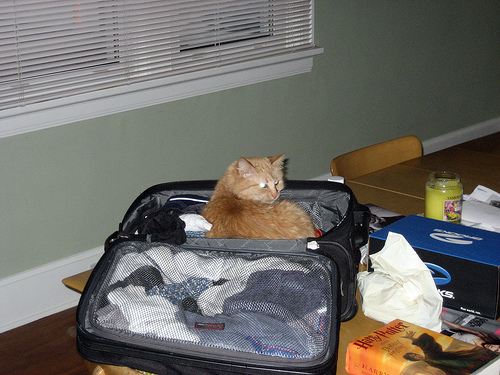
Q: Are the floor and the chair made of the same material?
A: Yes, both the floor and the chair are made of wood.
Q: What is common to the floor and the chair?
A: The material, both the floor and the chair are wooden.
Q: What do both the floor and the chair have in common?
A: The material, both the floor and the chair are wooden.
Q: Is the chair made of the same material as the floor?
A: Yes, both the chair and the floor are made of wood.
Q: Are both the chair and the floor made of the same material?
A: Yes, both the chair and the floor are made of wood.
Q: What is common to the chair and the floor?
A: The material, both the chair and the floor are wooden.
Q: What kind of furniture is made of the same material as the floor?
A: The chair is made of the same material as the floor.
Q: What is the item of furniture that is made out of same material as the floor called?
A: The piece of furniture is a chair.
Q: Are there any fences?
A: No, there are no fences.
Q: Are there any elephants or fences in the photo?
A: No, there are no fences or elephants.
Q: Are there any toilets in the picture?
A: No, there are no toilets.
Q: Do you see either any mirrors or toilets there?
A: No, there are no toilets or mirrors.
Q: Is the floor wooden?
A: Yes, the floor is wooden.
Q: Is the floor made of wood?
A: Yes, the floor is made of wood.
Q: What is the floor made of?
A: The floor is made of wood.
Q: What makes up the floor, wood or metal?
A: The floor is made of wood.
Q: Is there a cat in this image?
A: Yes, there is a cat.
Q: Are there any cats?
A: Yes, there is a cat.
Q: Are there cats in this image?
A: Yes, there is a cat.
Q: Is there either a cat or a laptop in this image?
A: Yes, there is a cat.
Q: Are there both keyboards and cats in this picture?
A: No, there is a cat but no keyboards.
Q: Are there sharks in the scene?
A: No, there are no sharks.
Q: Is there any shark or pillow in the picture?
A: No, there are no sharks or pillows.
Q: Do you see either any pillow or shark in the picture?
A: No, there are no sharks or pillows.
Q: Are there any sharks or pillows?
A: No, there are no sharks or pillows.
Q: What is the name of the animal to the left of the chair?
A: The animal is a cat.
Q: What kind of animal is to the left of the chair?
A: The animal is a cat.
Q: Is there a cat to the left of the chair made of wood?
A: Yes, there is a cat to the left of the chair.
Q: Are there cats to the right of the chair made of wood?
A: No, the cat is to the left of the chair.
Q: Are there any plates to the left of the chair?
A: No, there is a cat to the left of the chair.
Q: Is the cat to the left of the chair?
A: Yes, the cat is to the left of the chair.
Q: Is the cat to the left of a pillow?
A: No, the cat is to the left of the chair.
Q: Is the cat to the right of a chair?
A: No, the cat is to the left of a chair.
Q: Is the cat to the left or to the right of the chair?
A: The cat is to the left of the chair.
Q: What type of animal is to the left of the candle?
A: The animal is a cat.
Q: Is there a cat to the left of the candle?
A: Yes, there is a cat to the left of the candle.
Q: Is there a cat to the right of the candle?
A: No, the cat is to the left of the candle.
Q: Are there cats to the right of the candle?
A: No, the cat is to the left of the candle.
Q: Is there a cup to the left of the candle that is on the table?
A: No, there is a cat to the left of the candle.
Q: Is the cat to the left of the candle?
A: Yes, the cat is to the left of the candle.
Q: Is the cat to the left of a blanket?
A: No, the cat is to the left of the candle.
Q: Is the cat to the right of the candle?
A: No, the cat is to the left of the candle.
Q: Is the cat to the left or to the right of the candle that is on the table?
A: The cat is to the left of the candle.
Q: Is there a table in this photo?
A: Yes, there is a table.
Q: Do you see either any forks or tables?
A: Yes, there is a table.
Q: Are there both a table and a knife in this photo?
A: No, there is a table but no knives.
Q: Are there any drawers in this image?
A: No, there are no drawers.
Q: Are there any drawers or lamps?
A: No, there are no drawers or lamps.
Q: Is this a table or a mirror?
A: This is a table.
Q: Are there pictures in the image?
A: No, there are no pictures.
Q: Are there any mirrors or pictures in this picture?
A: No, there are no pictures or mirrors.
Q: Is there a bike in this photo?
A: No, there are no bikes.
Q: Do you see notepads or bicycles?
A: No, there are no bicycles or notepads.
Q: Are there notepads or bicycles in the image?
A: No, there are no bicycles or notepads.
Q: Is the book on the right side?
A: Yes, the book is on the right of the image.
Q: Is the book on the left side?
A: No, the book is on the right of the image.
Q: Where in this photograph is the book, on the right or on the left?
A: The book is on the right of the image.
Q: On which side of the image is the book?
A: The book is on the right of the image.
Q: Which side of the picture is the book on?
A: The book is on the right of the image.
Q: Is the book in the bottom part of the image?
A: Yes, the book is in the bottom of the image.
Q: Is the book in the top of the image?
A: No, the book is in the bottom of the image.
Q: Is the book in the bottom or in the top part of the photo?
A: The book is in the bottom of the image.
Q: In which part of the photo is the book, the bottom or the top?
A: The book is in the bottom of the image.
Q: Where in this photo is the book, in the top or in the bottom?
A: The book is in the bottom of the image.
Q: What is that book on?
A: The book is on the table.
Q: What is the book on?
A: The book is on the table.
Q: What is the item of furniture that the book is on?
A: The piece of furniture is a table.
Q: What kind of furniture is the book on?
A: The book is on the table.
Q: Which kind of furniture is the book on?
A: The book is on the table.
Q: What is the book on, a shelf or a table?
A: The book is on a table.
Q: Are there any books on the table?
A: Yes, there is a book on the table.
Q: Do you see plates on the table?
A: No, there is a book on the table.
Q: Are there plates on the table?
A: No, there is a book on the table.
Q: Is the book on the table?
A: Yes, the book is on the table.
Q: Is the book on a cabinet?
A: No, the book is on the table.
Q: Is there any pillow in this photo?
A: No, there are no pillows.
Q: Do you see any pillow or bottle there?
A: No, there are no pillows or bottles.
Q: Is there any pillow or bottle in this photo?
A: No, there are no pillows or bottles.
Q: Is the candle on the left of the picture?
A: No, the candle is on the right of the image.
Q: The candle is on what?
A: The candle is on the table.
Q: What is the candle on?
A: The candle is on the table.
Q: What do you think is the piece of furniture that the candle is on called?
A: The piece of furniture is a table.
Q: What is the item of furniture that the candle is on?
A: The piece of furniture is a table.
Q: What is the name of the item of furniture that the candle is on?
A: The piece of furniture is a table.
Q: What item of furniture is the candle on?
A: The candle is on the table.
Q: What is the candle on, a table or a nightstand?
A: The candle is on a table.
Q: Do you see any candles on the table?
A: Yes, there is a candle on the table.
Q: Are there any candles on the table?
A: Yes, there is a candle on the table.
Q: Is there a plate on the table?
A: No, there is a candle on the table.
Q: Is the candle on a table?
A: Yes, the candle is on a table.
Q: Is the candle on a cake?
A: No, the candle is on a table.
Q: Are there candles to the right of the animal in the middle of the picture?
A: Yes, there is a candle to the right of the cat.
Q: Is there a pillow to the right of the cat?
A: No, there is a candle to the right of the cat.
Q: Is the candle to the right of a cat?
A: Yes, the candle is to the right of a cat.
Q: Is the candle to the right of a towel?
A: No, the candle is to the right of a cat.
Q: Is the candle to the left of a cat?
A: No, the candle is to the right of a cat.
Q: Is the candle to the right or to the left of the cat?
A: The candle is to the right of the cat.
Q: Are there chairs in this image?
A: Yes, there is a chair.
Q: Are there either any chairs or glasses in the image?
A: Yes, there is a chair.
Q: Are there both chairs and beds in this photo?
A: No, there is a chair but no beds.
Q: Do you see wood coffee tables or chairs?
A: Yes, there is a wood chair.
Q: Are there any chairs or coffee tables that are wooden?
A: Yes, the chair is wooden.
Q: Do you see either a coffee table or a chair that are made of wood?
A: Yes, the chair is made of wood.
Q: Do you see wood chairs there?
A: Yes, there is a wood chair.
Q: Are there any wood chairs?
A: Yes, there is a wood chair.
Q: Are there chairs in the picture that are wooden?
A: Yes, there is a chair that is wooden.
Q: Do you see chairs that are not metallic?
A: Yes, there is a wooden chair.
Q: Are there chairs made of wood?
A: Yes, there is a chair that is made of wood.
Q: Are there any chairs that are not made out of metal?
A: Yes, there is a chair that is made of wood.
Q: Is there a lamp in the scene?
A: No, there are no lamps.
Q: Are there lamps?
A: No, there are no lamps.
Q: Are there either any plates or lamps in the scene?
A: No, there are no lamps or plates.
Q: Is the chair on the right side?
A: Yes, the chair is on the right of the image.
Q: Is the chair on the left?
A: No, the chair is on the right of the image.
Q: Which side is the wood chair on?
A: The chair is on the right of the image.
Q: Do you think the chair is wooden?
A: Yes, the chair is wooden.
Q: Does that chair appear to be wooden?
A: Yes, the chair is wooden.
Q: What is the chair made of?
A: The chair is made of wood.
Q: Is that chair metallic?
A: No, the chair is wooden.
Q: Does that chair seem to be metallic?
A: No, the chair is wooden.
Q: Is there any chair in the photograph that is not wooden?
A: No, there is a chair but it is wooden.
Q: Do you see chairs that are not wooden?
A: No, there is a chair but it is wooden.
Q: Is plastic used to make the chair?
A: No, the chair is made of wood.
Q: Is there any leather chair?
A: No, there is a chair but it is made of wood.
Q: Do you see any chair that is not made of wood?
A: No, there is a chair but it is made of wood.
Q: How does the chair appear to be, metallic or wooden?
A: The chair is wooden.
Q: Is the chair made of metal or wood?
A: The chair is made of wood.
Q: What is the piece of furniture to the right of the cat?
A: The piece of furniture is a chair.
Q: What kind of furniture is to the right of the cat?
A: The piece of furniture is a chair.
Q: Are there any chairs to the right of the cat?
A: Yes, there is a chair to the right of the cat.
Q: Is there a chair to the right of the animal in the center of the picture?
A: Yes, there is a chair to the right of the cat.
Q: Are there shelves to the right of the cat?
A: No, there is a chair to the right of the cat.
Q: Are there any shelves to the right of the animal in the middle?
A: No, there is a chair to the right of the cat.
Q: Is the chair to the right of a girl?
A: No, the chair is to the right of the cat.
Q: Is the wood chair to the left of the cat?
A: No, the chair is to the right of the cat.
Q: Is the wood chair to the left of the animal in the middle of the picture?
A: No, the chair is to the right of the cat.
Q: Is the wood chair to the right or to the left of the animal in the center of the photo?
A: The chair is to the right of the cat.